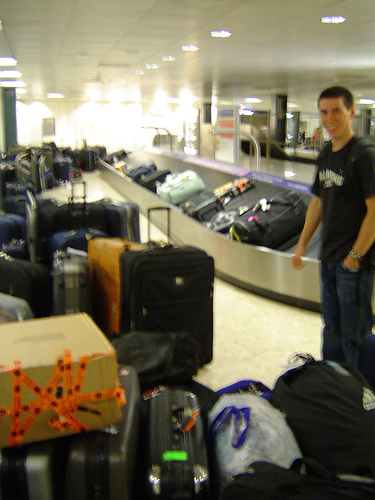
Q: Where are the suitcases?
A: In airport.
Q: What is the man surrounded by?
A: Suitcases.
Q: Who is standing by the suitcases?
A: The man in black.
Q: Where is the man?
A: In an airport.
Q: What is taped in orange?
A: The cardboard box.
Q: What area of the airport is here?
A: The baggage area.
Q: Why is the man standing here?
A: For luggage.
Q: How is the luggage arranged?
A: In piles.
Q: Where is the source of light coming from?
A: The ceiling.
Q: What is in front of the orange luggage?
A: Black luggage.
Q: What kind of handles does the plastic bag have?
A: Blue.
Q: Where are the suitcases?
A: In the airport.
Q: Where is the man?
A: On front suitcases.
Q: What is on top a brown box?
A: Yellow tape.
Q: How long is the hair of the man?
A: Short.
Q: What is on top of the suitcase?
A: Tags.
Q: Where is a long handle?
A: Over a suitcase.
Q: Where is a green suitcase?
A: On a carousel.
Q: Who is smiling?
A: A young man in jeans and a black shirt.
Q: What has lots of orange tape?
A: A cardboard box.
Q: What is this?
A: A luggage area at the airport.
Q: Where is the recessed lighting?
A: On the ceiling.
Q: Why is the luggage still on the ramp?
A: It hasn't been claimed yet.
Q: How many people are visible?
A: One.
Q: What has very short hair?
A: A smiling man.